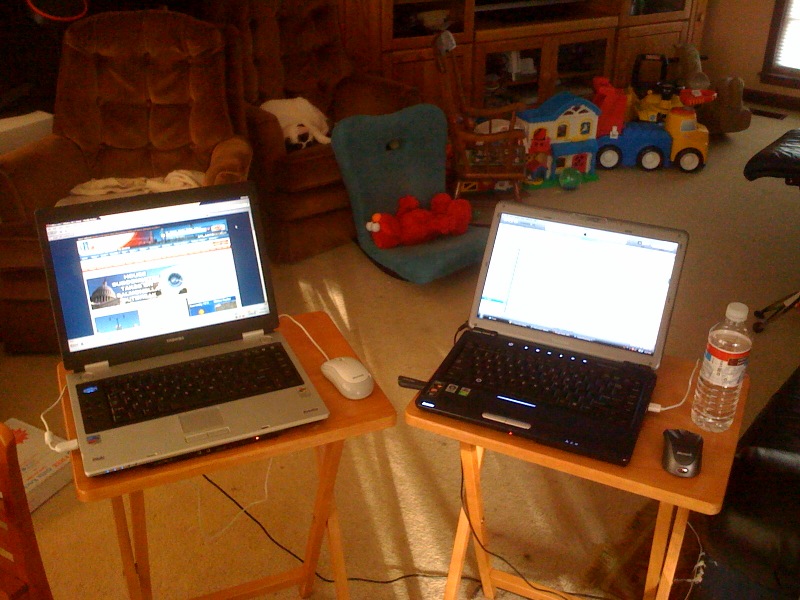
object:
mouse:
[320, 356, 374, 400]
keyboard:
[444, 338, 650, 428]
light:
[496, 396, 537, 408]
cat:
[260, 93, 331, 148]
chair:
[224, 0, 420, 263]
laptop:
[416, 201, 688, 466]